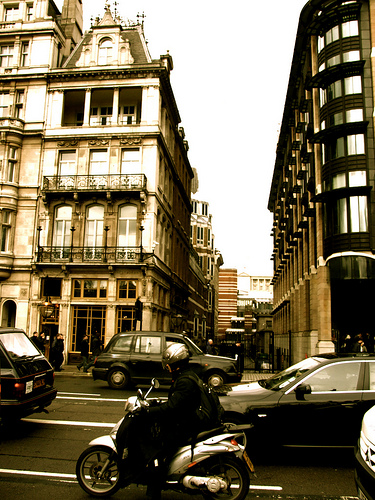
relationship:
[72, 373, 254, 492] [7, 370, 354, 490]
motorcycle on street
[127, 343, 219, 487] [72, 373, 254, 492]
person riding a motorcycle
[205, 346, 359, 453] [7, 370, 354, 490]
car on street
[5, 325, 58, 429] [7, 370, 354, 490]
car on street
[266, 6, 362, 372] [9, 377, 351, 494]
building across street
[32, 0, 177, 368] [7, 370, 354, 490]
building across street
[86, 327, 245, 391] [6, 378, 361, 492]
car on road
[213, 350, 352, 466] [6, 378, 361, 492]
car on road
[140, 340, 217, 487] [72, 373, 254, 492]
person riding on motorcycle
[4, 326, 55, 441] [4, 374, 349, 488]
car on road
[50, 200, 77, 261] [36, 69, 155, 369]
window on storefront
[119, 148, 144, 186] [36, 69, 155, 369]
window on storefront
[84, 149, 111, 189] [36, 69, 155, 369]
window on storefront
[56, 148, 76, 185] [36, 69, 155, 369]
window on storefront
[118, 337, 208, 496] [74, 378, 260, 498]
man riding motorcycle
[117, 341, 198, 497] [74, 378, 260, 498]
man riding motorcycle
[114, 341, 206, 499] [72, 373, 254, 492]
man riding motorcycle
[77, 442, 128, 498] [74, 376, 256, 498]
wheel on front of scooter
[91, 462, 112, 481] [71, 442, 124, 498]
rotor on wheel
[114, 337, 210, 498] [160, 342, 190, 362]
person wearing helmet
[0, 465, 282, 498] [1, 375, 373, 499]
line painted on street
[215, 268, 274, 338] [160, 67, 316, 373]
buildings down alley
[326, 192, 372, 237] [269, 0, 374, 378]
window on corner of building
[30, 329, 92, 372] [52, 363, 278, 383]
pedestrians on sidewalk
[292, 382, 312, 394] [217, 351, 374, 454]
mirror on car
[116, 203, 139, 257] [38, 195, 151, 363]
window on storefront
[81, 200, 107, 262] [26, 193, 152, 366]
window on storefront